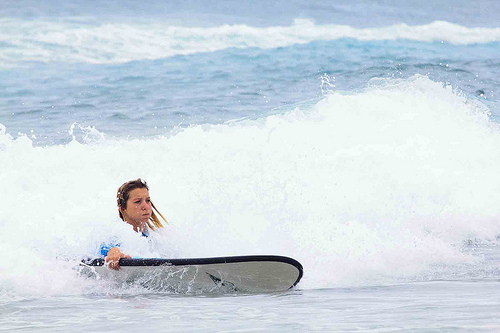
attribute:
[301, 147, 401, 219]
water — clear, white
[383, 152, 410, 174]
ground — clear, white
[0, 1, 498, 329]
water — clear, white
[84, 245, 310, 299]
surfboard — black, white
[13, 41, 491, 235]
water — clear, white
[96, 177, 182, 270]
woman — wet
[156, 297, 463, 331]
sea water — white, clear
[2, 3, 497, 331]
photo — taken, daytime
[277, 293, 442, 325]
water — white, clear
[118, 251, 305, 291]
surfboard — black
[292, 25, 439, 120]
water — blue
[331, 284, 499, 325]
water — clear, white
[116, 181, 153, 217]
hair — wet